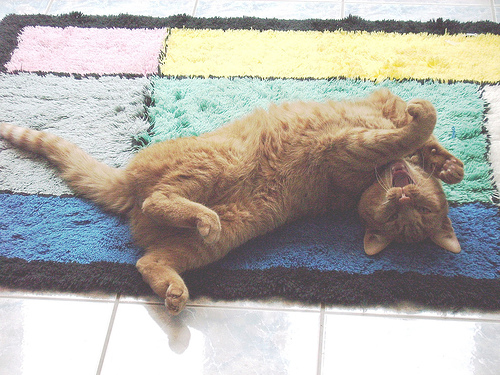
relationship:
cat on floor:
[0, 91, 460, 320] [0, 2, 496, 371]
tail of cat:
[4, 121, 126, 215] [0, 91, 460, 320]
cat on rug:
[0, 91, 460, 320] [3, 13, 500, 310]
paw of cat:
[403, 98, 438, 134] [0, 91, 460, 320]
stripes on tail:
[6, 123, 53, 157] [4, 121, 126, 215]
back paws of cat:
[134, 196, 223, 316] [0, 91, 460, 320]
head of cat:
[351, 161, 460, 262] [0, 91, 460, 320]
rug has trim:
[3, 13, 500, 310] [0, 11, 499, 309]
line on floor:
[86, 295, 128, 372] [0, 2, 496, 371]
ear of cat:
[363, 228, 387, 257] [0, 91, 460, 320]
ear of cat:
[439, 229, 468, 256] [0, 91, 460, 320]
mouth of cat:
[388, 162, 410, 191] [0, 91, 460, 320]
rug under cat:
[3, 13, 500, 310] [0, 91, 460, 320]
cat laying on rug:
[0, 91, 460, 320] [3, 13, 500, 310]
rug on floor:
[3, 13, 500, 310] [0, 2, 496, 371]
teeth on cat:
[392, 167, 406, 177] [0, 91, 460, 320]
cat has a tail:
[0, 91, 460, 320] [4, 121, 126, 215]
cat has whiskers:
[0, 91, 460, 320] [373, 157, 437, 192]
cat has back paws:
[0, 91, 460, 320] [134, 196, 223, 316]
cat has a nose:
[0, 91, 460, 320] [399, 191, 410, 204]